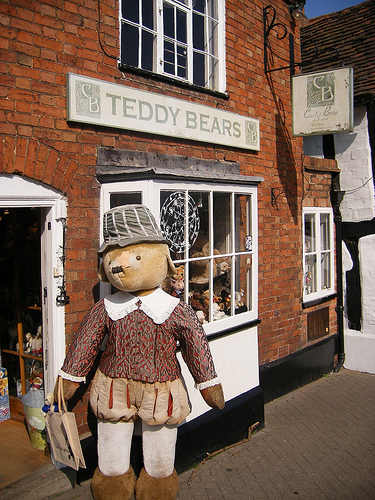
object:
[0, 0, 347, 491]
building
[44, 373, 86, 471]
bag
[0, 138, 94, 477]
door frame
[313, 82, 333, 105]
ground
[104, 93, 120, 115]
letter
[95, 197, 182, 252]
hat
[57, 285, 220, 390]
shirt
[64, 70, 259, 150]
sign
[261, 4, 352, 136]
sign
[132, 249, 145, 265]
eye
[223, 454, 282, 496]
ground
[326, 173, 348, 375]
pipe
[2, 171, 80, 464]
door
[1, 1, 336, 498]
place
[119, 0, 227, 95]
window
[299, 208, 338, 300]
window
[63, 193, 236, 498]
teddy bear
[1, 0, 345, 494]
store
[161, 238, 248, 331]
teddy bears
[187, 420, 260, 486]
stick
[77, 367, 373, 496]
sidewalk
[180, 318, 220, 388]
arm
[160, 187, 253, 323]
window